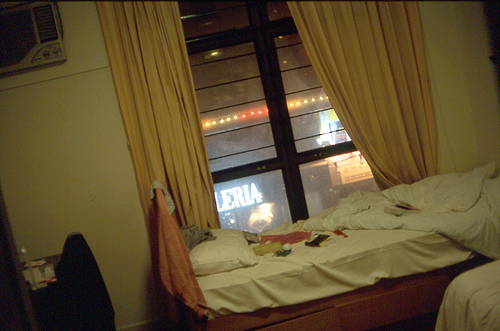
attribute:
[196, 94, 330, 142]
lights — bright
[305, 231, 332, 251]
book — black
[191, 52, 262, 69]
bar — small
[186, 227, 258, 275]
pillow — white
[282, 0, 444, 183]
curtain — yellow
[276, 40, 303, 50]
bar — small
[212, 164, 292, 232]
sign — bright blue, neon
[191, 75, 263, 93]
bar — small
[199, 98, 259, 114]
bar — small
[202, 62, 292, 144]
bar — small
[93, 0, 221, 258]
curtain — yellow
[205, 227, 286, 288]
pillow — white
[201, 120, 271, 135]
bar — small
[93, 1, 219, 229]
curtain — yellow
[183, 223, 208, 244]
shirt — gray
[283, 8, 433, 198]
curtain — yellow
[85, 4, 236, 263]
curtain — yellow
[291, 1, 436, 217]
curtain — yellow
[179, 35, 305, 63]
bar — small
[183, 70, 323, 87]
bar — small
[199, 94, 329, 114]
bar — small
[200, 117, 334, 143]
bar — small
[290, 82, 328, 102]
bar — small